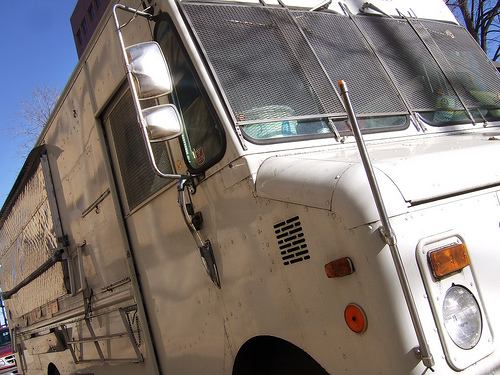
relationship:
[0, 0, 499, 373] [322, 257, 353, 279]
van has a signal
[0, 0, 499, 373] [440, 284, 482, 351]
van has a headlight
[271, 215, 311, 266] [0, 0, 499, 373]
vent on side of van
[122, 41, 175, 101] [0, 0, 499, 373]
rear view mirror on van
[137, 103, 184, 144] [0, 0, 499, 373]
rear view mirror on van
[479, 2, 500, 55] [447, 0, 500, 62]
branch on tree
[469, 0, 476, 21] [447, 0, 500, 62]
branch on tree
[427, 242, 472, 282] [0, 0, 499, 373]
light on van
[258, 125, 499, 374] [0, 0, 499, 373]
front of van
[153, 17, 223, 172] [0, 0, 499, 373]
window on van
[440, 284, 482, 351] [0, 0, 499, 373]
headlight on van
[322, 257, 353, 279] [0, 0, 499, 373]
signal on van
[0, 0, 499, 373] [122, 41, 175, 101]
van has rear view mirror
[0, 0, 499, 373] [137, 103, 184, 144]
van has rear view mirror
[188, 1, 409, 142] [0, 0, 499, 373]
windshield on van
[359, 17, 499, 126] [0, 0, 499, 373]
windshield on van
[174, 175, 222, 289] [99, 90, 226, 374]
handel on door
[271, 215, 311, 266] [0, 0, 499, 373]
vent on van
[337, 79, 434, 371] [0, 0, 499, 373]
pole on van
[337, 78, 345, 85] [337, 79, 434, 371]
tip on pole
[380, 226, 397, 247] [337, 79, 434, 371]
brackets on pole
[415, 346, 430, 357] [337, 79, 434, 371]
brackets on pole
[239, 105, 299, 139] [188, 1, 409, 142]
bucket in windshield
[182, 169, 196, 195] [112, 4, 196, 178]
bracket on holding mirrors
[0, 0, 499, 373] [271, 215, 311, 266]
van has a vent